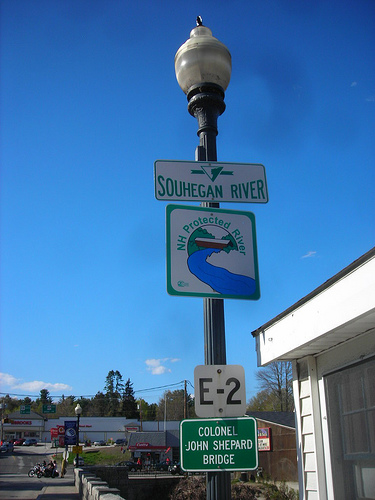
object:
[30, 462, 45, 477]
motorcycle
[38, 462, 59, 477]
motorcycle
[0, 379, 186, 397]
wires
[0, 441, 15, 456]
cars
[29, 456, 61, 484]
motorcycles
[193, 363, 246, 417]
street sign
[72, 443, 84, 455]
street sign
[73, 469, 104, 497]
wall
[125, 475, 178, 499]
ravine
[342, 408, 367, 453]
window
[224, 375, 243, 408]
number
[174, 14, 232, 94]
lamp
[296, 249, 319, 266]
white cloud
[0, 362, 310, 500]
outside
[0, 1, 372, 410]
sky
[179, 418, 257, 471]
sign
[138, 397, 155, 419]
green trees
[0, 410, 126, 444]
shopping center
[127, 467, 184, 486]
bridge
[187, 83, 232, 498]
light post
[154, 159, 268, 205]
signs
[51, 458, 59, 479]
motorcyclists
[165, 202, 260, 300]
sign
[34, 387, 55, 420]
tree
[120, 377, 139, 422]
tree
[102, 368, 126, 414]
tree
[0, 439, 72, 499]
road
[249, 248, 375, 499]
building